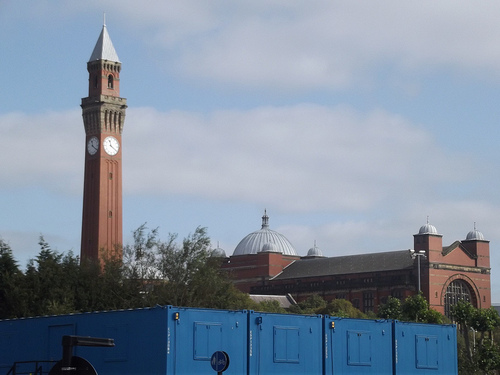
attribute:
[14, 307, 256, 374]
trailer — four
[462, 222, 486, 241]
mound — two small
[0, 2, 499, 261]
sky — blue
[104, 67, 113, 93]
window — big,  building's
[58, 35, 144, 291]
tower — clock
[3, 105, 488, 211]
cloud — white ,  white 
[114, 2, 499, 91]
cloud —  white , white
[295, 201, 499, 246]
cloud —  white 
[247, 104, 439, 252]
sky — blue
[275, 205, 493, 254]
cloud — white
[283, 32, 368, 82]
cloud — white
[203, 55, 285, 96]
clouds — white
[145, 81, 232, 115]
sky — blue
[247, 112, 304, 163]
clouds — white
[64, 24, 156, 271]
clock tower — brown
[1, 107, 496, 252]
clouds — white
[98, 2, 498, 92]
clouds — white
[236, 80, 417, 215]
clouds — white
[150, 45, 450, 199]
sky — blue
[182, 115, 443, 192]
clouds — white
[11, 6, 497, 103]
clouds —  white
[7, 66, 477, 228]
clouds —  white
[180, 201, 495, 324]
building — horizontal, brick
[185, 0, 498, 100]
white clouds — puffy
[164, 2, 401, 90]
cloud — white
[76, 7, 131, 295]
tower — brick, clock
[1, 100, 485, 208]
clouds — white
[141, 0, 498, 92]
clouds — white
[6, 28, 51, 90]
clouds —  white 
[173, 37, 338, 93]
cloud — white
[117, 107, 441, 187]
cloud — white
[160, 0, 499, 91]
cloud — white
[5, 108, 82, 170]
cloud — white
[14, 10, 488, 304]
sky — blue,  blue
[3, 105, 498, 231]
clouds — are white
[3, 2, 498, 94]
clouds — are white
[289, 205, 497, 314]
cloud — white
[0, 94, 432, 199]
cloud — white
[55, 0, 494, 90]
cloud — white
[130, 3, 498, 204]
sky —  blue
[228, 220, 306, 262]
mound — rounded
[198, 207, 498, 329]
building — top